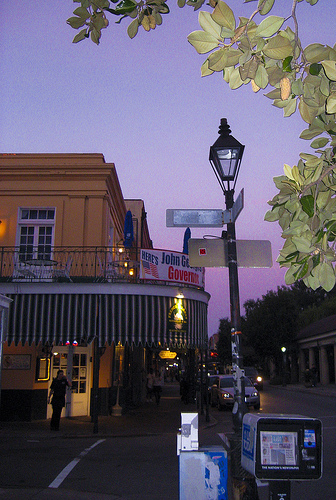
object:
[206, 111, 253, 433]
street light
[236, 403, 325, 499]
newspaper stand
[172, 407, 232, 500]
newspaper stand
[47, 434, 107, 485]
line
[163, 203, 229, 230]
street sign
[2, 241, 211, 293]
balcony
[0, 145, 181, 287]
rooftop area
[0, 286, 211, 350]
banner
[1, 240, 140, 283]
patio set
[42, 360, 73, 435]
woman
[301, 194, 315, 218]
leaf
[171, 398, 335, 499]
corner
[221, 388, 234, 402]
headlight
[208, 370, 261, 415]
car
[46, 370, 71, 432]
black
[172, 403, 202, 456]
top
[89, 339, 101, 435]
pillar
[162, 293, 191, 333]
sign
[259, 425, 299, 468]
newspaper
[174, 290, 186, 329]
light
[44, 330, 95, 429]
doorway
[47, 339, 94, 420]
door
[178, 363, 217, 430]
curb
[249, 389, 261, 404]
headlight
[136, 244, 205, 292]
campaign sign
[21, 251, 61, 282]
table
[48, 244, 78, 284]
chair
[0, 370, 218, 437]
sidewalk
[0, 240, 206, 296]
fence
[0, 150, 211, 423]
restaurant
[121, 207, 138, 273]
umbrella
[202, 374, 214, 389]
car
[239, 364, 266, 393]
car